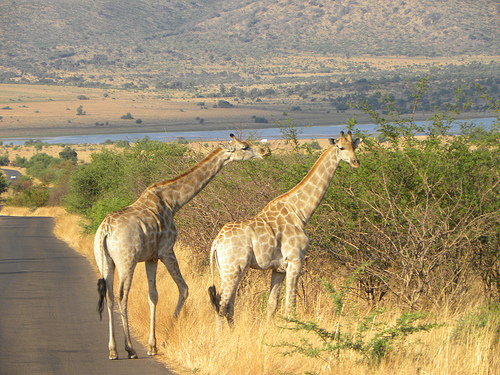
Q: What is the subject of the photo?
A: Animals.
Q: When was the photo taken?
A: Daytime.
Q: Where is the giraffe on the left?
A: Road.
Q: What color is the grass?
A: Brown.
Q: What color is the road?
A: Gray.